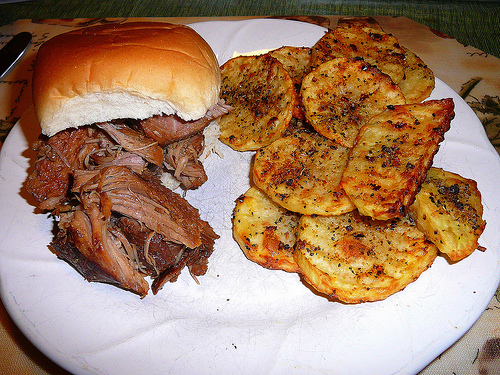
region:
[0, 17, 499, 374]
A delicious served meal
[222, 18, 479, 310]
Slices of roast potatoes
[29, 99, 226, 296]
The brown grilled meat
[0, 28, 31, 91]
A partially blocked cutlerly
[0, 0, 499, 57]
The green top background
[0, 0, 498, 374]
A served main course dish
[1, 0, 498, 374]
Served meal on a table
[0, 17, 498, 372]
The rounded white plate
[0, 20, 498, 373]
A patterned table background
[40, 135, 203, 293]
pulled pork on the plate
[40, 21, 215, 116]
the bun on the pork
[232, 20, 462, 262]
potato slices on the plate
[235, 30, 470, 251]
potato slices are fried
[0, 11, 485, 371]
the plate is white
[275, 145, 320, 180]
seasoning on the potato slice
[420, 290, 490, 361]
the edge of the plate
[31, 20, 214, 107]
the bun is brown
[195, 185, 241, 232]
cracks on the plate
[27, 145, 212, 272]
the pork is sinewy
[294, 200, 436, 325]
This is a piece of food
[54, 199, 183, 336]
This is a piece of food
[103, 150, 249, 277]
This is a piece of food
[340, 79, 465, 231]
This is a piece of food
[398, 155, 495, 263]
This is a piece of food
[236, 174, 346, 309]
This is a piece of food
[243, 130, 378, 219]
This is a piece of food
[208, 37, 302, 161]
This is a piece of food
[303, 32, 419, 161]
This is a piece of food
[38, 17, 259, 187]
This is a piece of food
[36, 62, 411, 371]
a plate of snacks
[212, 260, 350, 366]
plate is white in color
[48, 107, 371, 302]
food is delicious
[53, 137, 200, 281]
meat is brown in color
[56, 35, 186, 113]
bread is brown in color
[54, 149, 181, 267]
meat is apetising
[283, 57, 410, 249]
crips are brown in color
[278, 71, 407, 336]
srips are delicious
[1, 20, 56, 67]
knife is silvery in color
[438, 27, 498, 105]
table is brown in color